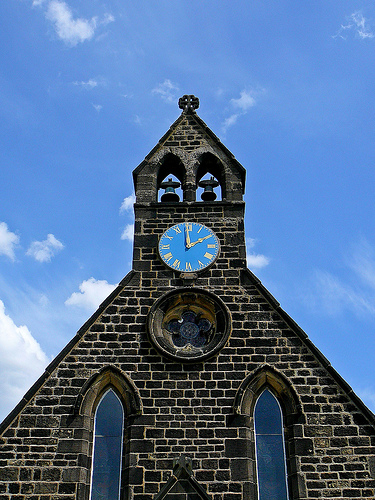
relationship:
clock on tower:
[157, 221, 221, 271] [131, 94, 249, 274]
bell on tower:
[158, 175, 181, 203] [131, 94, 249, 274]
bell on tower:
[196, 177, 223, 200] [131, 94, 249, 274]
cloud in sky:
[1, 220, 52, 426] [2, 3, 372, 427]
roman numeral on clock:
[171, 224, 183, 234] [157, 221, 221, 271]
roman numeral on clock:
[196, 223, 206, 234] [157, 221, 221, 271]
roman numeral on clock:
[207, 244, 223, 251] [157, 221, 221, 271]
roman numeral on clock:
[172, 258, 182, 271] [157, 221, 221, 271]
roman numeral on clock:
[157, 244, 175, 252] [157, 221, 221, 271]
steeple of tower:
[177, 96, 199, 115] [131, 94, 249, 274]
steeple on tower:
[177, 96, 199, 115] [131, 94, 249, 274]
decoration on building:
[147, 285, 233, 363] [6, 91, 372, 498]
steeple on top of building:
[177, 96, 199, 115] [6, 91, 372, 498]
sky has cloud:
[2, 3, 372, 427] [1, 220, 52, 426]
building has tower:
[6, 91, 372, 498] [131, 94, 249, 274]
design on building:
[147, 285, 233, 363] [6, 91, 372, 498]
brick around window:
[71, 362, 144, 498] [247, 387, 293, 499]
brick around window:
[232, 361, 320, 500] [247, 387, 293, 499]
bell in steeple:
[158, 175, 181, 203] [177, 96, 199, 115]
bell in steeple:
[196, 177, 223, 200] [177, 96, 199, 115]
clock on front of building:
[157, 221, 221, 271] [6, 91, 372, 498]